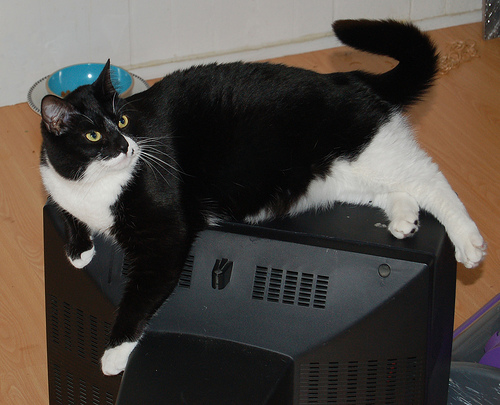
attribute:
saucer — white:
[21, 71, 59, 111]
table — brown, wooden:
[461, 55, 488, 204]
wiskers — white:
[131, 131, 188, 177]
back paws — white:
[378, 199, 498, 269]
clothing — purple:
[461, 295, 496, 383]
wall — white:
[134, 6, 277, 41]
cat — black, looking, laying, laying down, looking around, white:
[31, 14, 491, 290]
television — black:
[33, 242, 465, 397]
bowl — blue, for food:
[46, 60, 139, 92]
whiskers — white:
[131, 131, 188, 177]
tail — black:
[325, 11, 443, 98]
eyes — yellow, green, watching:
[76, 111, 134, 141]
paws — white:
[378, 199, 498, 269]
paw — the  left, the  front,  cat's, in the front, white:
[55, 233, 112, 272]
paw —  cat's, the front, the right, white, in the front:
[93, 323, 141, 380]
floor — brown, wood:
[0, 85, 495, 311]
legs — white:
[325, 126, 498, 273]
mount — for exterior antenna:
[205, 251, 238, 290]